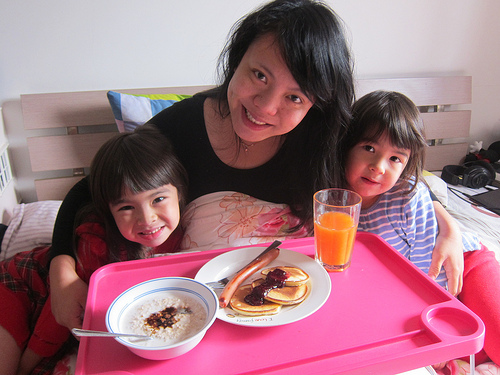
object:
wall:
[0, 2, 497, 174]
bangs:
[360, 100, 425, 147]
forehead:
[362, 120, 412, 152]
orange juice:
[314, 211, 359, 269]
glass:
[313, 186, 362, 270]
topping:
[145, 305, 174, 330]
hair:
[222, 0, 358, 237]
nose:
[367, 157, 386, 176]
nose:
[138, 205, 156, 225]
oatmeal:
[119, 293, 207, 347]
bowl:
[105, 275, 219, 361]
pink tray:
[71, 230, 484, 374]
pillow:
[107, 92, 188, 139]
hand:
[429, 219, 466, 296]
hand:
[47, 252, 87, 335]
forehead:
[244, 38, 318, 79]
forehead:
[106, 162, 174, 197]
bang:
[277, 30, 340, 107]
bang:
[100, 135, 178, 205]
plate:
[195, 246, 335, 327]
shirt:
[49, 94, 330, 258]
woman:
[49, 0, 464, 348]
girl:
[0, 129, 190, 374]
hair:
[353, 90, 424, 147]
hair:
[93, 131, 184, 200]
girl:
[338, 85, 498, 372]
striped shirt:
[355, 170, 480, 290]